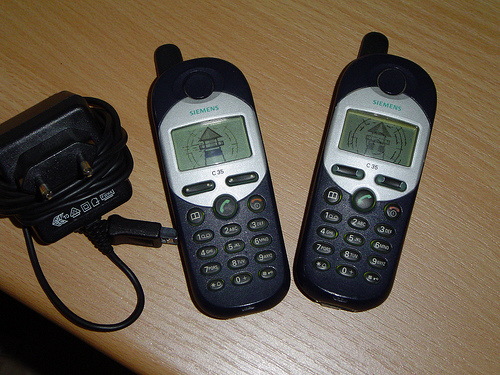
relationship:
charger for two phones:
[0, 91, 180, 331] [150, 31, 437, 319]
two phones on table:
[150, 31, 437, 319] [0, 0, 500, 374]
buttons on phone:
[313, 165, 406, 282] [295, 32, 438, 313]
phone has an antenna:
[295, 32, 438, 313] [357, 31, 389, 56]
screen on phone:
[337, 110, 419, 168] [295, 32, 438, 313]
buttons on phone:
[354, 187, 374, 210] [295, 32, 438, 313]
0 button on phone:
[338, 265, 360, 278] [295, 32, 438, 313]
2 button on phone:
[350, 217, 369, 231] [295, 32, 438, 313]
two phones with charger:
[150, 31, 437, 319] [0, 91, 180, 331]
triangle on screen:
[368, 123, 392, 139] [337, 110, 419, 168]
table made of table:
[0, 0, 500, 374] [0, 0, 500, 374]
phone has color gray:
[295, 32, 438, 313] [323, 86, 429, 202]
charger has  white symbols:
[0, 91, 180, 331] [52, 189, 115, 228]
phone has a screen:
[295, 32, 438, 313] [337, 110, 419, 168]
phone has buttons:
[295, 32, 438, 313] [313, 165, 406, 282]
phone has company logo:
[295, 32, 438, 313] [371, 99, 404, 113]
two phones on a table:
[150, 31, 437, 319] [0, 0, 500, 374]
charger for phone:
[0, 91, 180, 331] [295, 32, 438, 313]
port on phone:
[317, 299, 353, 314] [295, 32, 438, 313]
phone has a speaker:
[295, 32, 438, 313] [376, 68, 408, 96]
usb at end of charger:
[158, 225, 180, 246] [0, 91, 180, 331]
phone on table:
[295, 32, 438, 313] [0, 0, 500, 374]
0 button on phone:
[232, 273, 252, 285] [150, 44, 292, 319]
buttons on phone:
[184, 172, 277, 292] [150, 44, 292, 319]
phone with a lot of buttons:
[295, 32, 438, 313] [313, 165, 406, 282]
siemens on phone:
[189, 105, 219, 116] [150, 44, 292, 319]